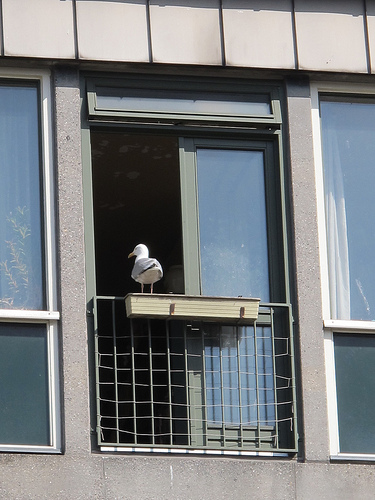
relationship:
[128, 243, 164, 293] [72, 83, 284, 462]
beak on window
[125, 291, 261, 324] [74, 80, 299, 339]
block on window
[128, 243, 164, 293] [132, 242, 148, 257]
beak has head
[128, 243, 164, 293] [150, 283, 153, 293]
beak has leg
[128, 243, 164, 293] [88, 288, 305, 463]
beak on windowsill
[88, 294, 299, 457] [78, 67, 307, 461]
fence outside window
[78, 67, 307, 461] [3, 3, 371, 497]
window of a building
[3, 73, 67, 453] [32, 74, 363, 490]
window with frame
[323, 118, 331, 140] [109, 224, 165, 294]
ground of a bird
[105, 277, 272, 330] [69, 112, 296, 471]
block in window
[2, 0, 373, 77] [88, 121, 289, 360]
tile above window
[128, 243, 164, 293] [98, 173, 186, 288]
beak faces interior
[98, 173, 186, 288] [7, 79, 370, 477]
interior of building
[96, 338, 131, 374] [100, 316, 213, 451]
hole in fence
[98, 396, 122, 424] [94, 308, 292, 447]
hole in fence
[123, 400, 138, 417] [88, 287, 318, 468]
hole in fence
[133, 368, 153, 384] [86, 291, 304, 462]
hole in fence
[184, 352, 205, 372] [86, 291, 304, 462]
hole in fence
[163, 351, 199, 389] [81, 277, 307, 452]
hole in fence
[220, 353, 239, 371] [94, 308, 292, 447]
hole in fence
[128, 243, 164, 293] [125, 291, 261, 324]
beak on block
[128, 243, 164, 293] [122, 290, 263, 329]
beak on box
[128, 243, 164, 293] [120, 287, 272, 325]
beak on box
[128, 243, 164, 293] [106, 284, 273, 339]
beak on box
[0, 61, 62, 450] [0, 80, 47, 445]
frame of window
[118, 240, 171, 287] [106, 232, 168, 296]
beak on bird